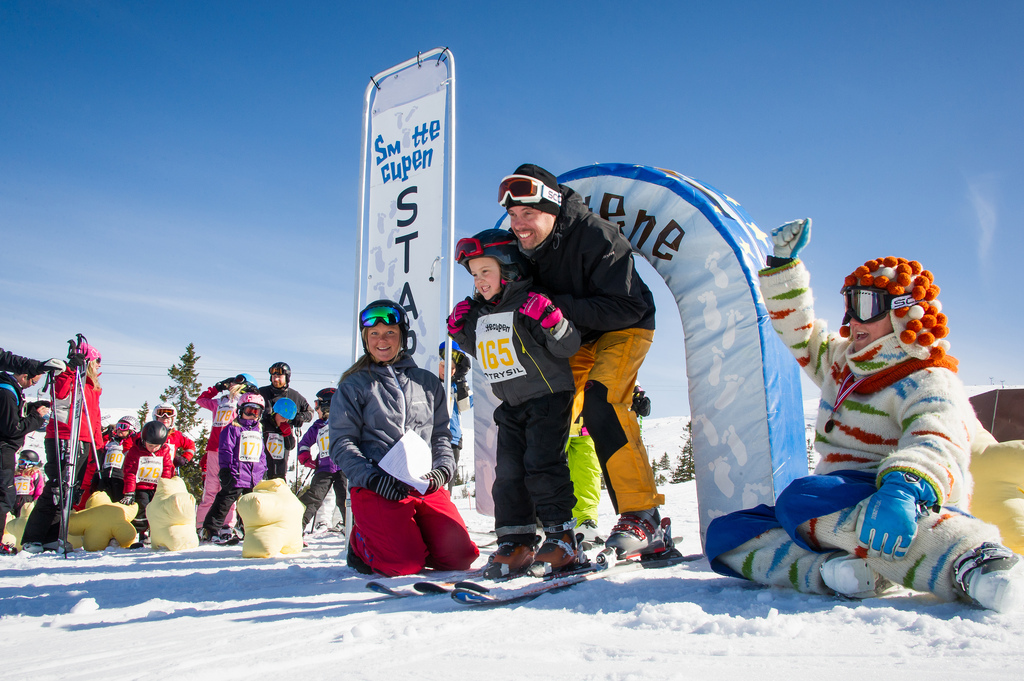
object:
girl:
[446, 229, 581, 577]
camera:
[51, 334, 93, 558]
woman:
[327, 300, 479, 577]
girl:
[461, 251, 504, 301]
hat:
[841, 256, 950, 359]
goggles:
[498, 174, 562, 207]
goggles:
[361, 299, 410, 327]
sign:
[475, 311, 527, 383]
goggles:
[841, 286, 927, 326]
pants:
[347, 487, 478, 576]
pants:
[570, 326, 667, 513]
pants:
[494, 390, 574, 536]